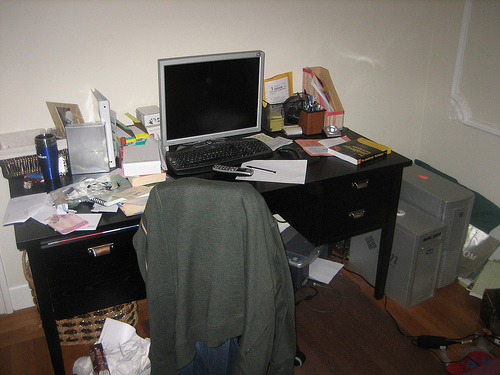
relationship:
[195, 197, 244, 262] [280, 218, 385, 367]
jacket on chair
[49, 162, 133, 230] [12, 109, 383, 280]
phone on desk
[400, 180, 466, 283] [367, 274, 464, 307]
computer on floor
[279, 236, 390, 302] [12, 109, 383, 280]
printer under desk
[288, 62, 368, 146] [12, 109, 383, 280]
magazine on desk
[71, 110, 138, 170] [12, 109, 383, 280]
notebook on desk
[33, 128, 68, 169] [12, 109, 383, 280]
container on desk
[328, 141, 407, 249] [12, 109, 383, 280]
drawer in desk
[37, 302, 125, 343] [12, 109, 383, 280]
basket under desk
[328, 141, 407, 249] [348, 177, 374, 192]
drawer with handle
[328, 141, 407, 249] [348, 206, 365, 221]
drawer with handle